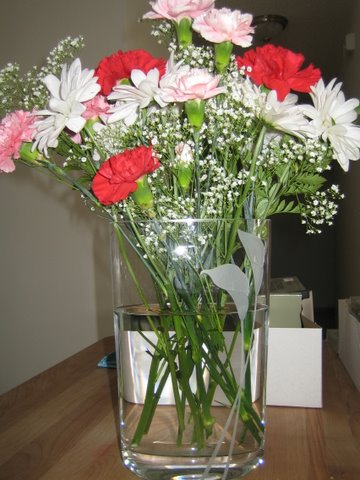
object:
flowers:
[92, 44, 320, 204]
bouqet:
[0, 0, 360, 448]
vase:
[110, 218, 272, 479]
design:
[199, 228, 266, 479]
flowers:
[0, 0, 256, 174]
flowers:
[29, 58, 360, 173]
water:
[113, 303, 269, 458]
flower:
[91, 145, 160, 206]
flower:
[26, 58, 101, 158]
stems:
[18, 18, 331, 450]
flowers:
[0, 0, 360, 263]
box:
[120, 289, 322, 406]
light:
[248, 15, 288, 43]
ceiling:
[191, 0, 359, 33]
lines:
[0, 334, 136, 478]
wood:
[0, 335, 360, 479]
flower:
[192, 7, 258, 49]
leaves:
[255, 172, 328, 217]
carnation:
[92, 49, 166, 97]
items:
[109, 215, 323, 479]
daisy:
[302, 78, 360, 172]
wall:
[0, 0, 175, 398]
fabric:
[97, 349, 117, 368]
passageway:
[192, 0, 360, 336]